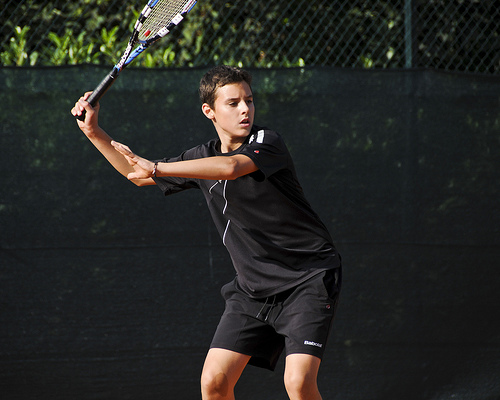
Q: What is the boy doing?
A: Swinging tennis racket.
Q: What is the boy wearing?
A: Black shirt with white design.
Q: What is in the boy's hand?
A: The racquet.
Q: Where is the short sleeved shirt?
A: On the boy.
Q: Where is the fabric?
A: On the chain link fence.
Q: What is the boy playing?
A: Tennis.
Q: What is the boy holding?
A: Racket.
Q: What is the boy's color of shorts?
A: Black.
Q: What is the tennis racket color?
A: Blue, white and black.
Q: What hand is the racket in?
A: Right hand.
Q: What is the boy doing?
A: Swinging.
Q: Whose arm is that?
A: A young man.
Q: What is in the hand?
A: Racquetball.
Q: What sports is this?
A: Tennis.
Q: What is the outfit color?
A: Black.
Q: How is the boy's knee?
A: Bend.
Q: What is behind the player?
A: Green fence.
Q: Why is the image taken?
A: Remembrance.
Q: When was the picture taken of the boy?
A: Daytime.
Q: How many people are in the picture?
A: One.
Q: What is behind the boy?
A: A fence.